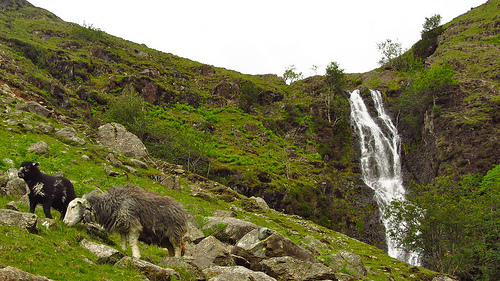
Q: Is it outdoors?
A: Yes, it is outdoors.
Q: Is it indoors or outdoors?
A: It is outdoors.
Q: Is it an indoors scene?
A: No, it is outdoors.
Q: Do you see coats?
A: Yes, there is a coat.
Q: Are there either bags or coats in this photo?
A: Yes, there is a coat.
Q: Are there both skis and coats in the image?
A: No, there is a coat but no skis.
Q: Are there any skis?
A: No, there are no skis.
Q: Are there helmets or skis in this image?
A: No, there are no skis or helmets.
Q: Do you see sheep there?
A: Yes, there is a sheep.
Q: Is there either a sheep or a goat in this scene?
A: Yes, there is a sheep.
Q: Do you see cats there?
A: No, there are no cats.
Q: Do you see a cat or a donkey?
A: No, there are no cats or donkeys.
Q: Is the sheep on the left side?
A: Yes, the sheep is on the left of the image.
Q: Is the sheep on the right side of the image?
A: No, the sheep is on the left of the image.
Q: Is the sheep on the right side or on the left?
A: The sheep is on the left of the image.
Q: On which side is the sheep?
A: The sheep is on the left of the image.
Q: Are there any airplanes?
A: No, there are no airplanes.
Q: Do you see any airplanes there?
A: No, there are no airplanes.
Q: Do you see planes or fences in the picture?
A: No, there are no planes or fences.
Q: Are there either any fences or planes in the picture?
A: No, there are no planes or fences.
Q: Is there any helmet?
A: No, there are no helmets.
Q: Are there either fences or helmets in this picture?
A: No, there are no helmets or fences.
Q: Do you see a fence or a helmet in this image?
A: No, there are no helmets or fences.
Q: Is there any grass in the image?
A: Yes, there is grass.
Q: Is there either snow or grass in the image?
A: Yes, there is grass.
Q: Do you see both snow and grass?
A: No, there is grass but no snow.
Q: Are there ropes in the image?
A: No, there are no ropes.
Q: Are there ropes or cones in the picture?
A: No, there are no ropes or cones.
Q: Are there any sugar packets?
A: No, there are no sugar packets.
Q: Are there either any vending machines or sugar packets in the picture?
A: No, there are no sugar packets or vending machines.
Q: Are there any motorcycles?
A: No, there are no motorcycles.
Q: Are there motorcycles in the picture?
A: No, there are no motorcycles.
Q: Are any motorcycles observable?
A: No, there are no motorcycles.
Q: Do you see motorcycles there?
A: No, there are no motorcycles.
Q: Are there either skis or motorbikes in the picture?
A: No, there are no motorbikes or skis.